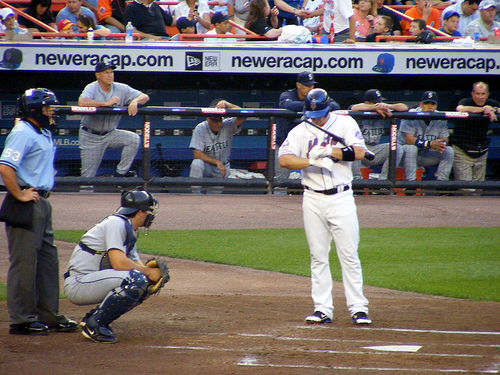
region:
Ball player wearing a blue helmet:
[298, 82, 338, 127]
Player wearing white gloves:
[303, 138, 334, 175]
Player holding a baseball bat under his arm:
[273, 110, 384, 176]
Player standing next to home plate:
[286, 242, 435, 359]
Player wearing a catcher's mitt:
[138, 250, 174, 300]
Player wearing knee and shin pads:
[83, 265, 153, 343]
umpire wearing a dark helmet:
[12, 82, 61, 139]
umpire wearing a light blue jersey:
[0, 110, 62, 201]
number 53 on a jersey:
[1, 141, 28, 170]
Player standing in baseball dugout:
[71, 55, 153, 187]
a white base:
[364, 338, 426, 352]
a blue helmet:
[301, 88, 331, 118]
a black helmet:
[117, 190, 150, 217]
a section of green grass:
[365, 228, 498, 301]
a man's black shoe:
[10, 315, 54, 335]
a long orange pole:
[377, 33, 455, 47]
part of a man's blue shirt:
[56, 7, 96, 33]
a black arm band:
[340, 144, 356, 161]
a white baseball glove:
[308, 138, 334, 159]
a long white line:
[295, 316, 497, 340]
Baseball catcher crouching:
[63, 186, 172, 348]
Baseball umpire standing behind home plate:
[1, 83, 81, 340]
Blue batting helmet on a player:
[297, 85, 332, 120]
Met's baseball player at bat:
[272, 83, 377, 326]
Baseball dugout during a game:
[1, 60, 496, 205]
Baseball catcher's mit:
[140, 255, 172, 296]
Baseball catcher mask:
[113, 186, 160, 241]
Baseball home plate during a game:
[355, 335, 425, 357]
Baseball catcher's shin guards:
[78, 268, 149, 348]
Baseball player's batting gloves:
[306, 141, 338, 173]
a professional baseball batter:
[277, 86, 374, 326]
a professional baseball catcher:
[61, 186, 171, 344]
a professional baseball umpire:
[0, 88, 62, 338]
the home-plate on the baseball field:
[360, 340, 423, 355]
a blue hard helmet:
[300, 88, 334, 119]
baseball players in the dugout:
[75, 56, 260, 186]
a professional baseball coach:
[450, 80, 495, 180]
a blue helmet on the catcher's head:
[115, 180, 156, 210]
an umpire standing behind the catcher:
[0, 85, 170, 345]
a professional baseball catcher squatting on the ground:
[62, 184, 171, 344]